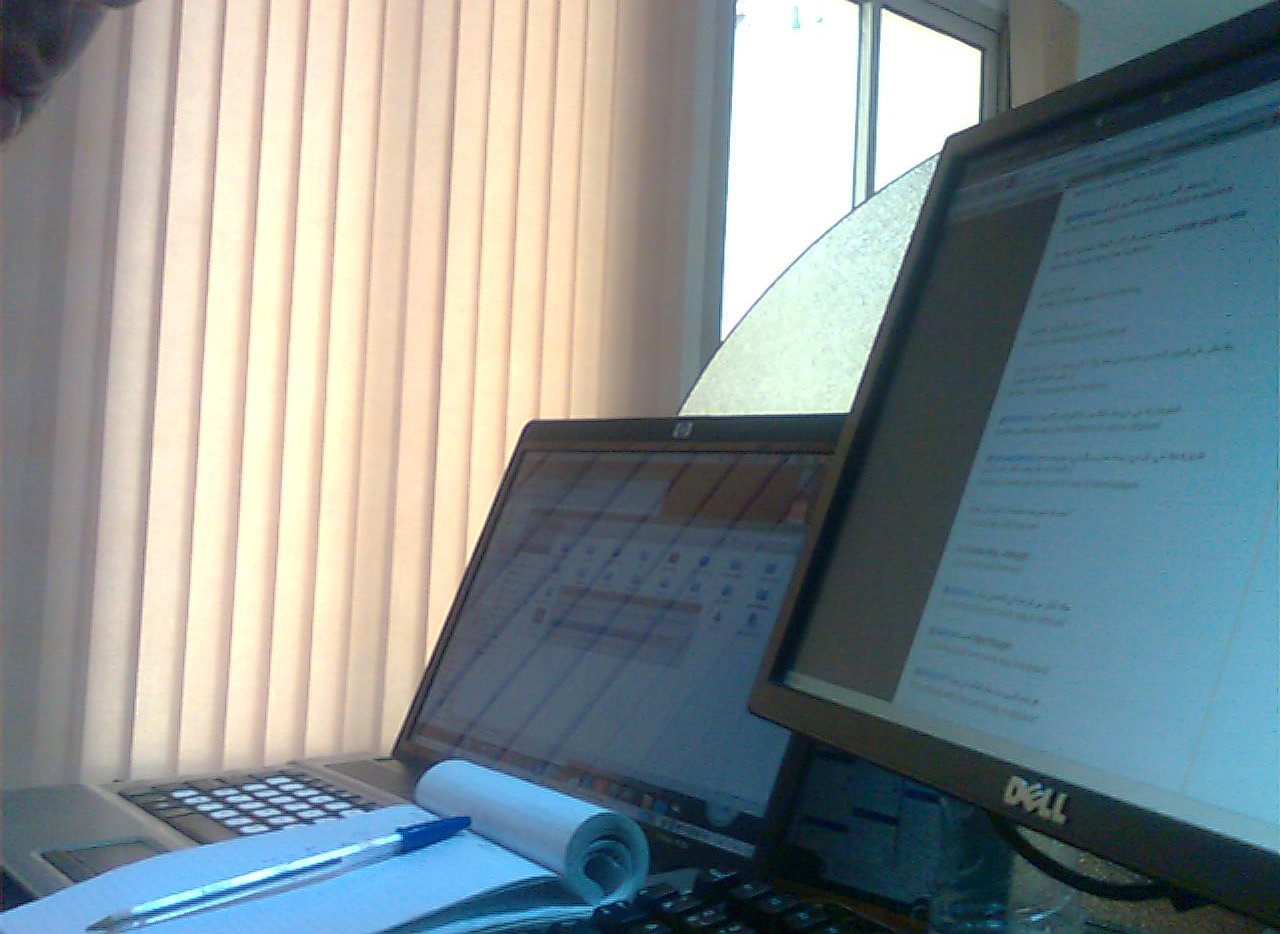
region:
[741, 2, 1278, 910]
Dell flatscreen computer monitor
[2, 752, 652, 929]
Pad of paper with a pen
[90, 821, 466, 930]
Pen resting on a pad of paper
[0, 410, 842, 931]
Laptop computer with a pad of paper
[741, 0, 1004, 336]
Sliding glass door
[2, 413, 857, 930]
Laptop using a Windows operating system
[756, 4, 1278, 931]
Computer monitor using an internet browser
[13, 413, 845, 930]
An HP laptop with touchpad and keyboard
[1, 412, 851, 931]
the laptop is open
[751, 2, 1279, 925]
the black screen leaning back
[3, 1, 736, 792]
the blinds in front of the sliding door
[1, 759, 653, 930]
the notepad on the laptop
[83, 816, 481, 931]
the blue pen on the notepad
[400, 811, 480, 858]
the blue cap on the pen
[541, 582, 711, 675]
the loading bad on the laptop screen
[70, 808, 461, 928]
Pen with blue ink.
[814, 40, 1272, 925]
Computer monitor by Dell.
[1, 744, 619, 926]
Pen and paper for taking notes.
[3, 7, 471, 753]
Window shades are closed.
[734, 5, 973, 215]
Large windows in office.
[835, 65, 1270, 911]
Black desktop computer monitor.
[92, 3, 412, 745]
Floor-to-ceiling window shades.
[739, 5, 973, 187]
Sunlight beams through windows.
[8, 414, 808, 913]
Laptop in working condition.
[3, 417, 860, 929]
An open laptop computer.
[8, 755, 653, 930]
An open blue notepad.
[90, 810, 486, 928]
A pen on a note pad.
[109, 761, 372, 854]
A half of a keyboard.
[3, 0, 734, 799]
A set of mini blinds.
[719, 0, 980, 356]
A couple of windows.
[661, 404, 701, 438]
A dell laptop computer logo.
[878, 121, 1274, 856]
A window on a computer.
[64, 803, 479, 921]
pen on the pad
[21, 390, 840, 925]
laptop on the table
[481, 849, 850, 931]
keyboard on the desk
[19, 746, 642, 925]
writing pad on the laptop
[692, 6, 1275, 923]
computer monitor on the desk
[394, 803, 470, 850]
blue cap on the pen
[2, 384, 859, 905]
laptop on the desk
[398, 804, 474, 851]
the blue plastic top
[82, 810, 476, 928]
the blue plastic pen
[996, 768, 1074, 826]
the silver dell logo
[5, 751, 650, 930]
the white notebook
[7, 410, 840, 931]
the open laptop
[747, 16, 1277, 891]
the dell compiter monitor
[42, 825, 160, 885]
the track pad of the laptop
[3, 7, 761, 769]
the plastic white hanging blinds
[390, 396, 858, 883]
the screen of the laptop is turn on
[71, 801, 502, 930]
the pen has blue cup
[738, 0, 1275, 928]
a flat screen computer monitor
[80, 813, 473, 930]
a blue ink pen